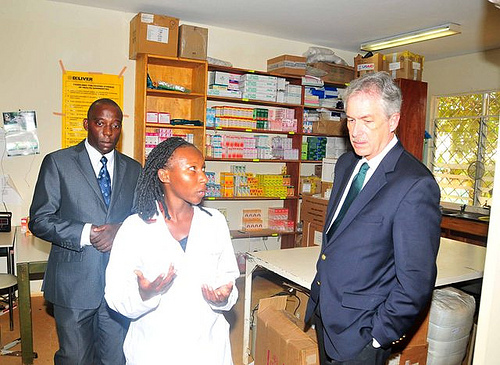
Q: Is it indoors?
A: Yes, it is indoors.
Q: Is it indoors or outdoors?
A: It is indoors.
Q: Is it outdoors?
A: No, it is indoors.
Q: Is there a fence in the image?
A: No, there are no fences.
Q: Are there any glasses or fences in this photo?
A: No, there are no fences or glasses.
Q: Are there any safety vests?
A: No, there are no safety vests.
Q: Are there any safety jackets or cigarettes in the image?
A: No, there are no safety jackets or cigarettes.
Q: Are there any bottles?
A: No, there are no bottles.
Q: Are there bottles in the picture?
A: No, there are no bottles.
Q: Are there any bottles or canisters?
A: No, there are no bottles or canisters.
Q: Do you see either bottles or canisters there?
A: No, there are no bottles or canisters.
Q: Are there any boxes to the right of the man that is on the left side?
A: Yes, there is a box to the right of the man.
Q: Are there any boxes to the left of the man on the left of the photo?
A: No, the box is to the right of the man.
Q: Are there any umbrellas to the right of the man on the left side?
A: No, there is a box to the right of the man.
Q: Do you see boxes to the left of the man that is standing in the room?
A: Yes, there is a box to the left of the man.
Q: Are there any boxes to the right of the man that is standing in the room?
A: No, the box is to the left of the man.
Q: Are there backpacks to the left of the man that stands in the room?
A: No, there is a box to the left of the man.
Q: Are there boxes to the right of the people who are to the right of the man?
A: Yes, there is a box to the right of the people.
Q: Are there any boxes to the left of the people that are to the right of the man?
A: No, the box is to the right of the people.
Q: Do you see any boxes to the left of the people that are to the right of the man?
A: No, the box is to the right of the people.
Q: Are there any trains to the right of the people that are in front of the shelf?
A: No, there is a box to the right of the people.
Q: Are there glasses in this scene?
A: No, there are no glasses.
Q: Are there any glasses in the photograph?
A: No, there are no glasses.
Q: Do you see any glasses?
A: No, there are no glasses.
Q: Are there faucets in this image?
A: No, there are no faucets.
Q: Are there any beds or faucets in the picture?
A: No, there are no faucets or beds.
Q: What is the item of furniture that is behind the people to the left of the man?
A: The piece of furniture is a shelf.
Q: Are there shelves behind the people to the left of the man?
A: Yes, there is a shelf behind the people.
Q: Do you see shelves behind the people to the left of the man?
A: Yes, there is a shelf behind the people.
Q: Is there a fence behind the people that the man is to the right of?
A: No, there is a shelf behind the people.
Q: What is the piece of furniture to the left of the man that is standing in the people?
A: The piece of furniture is a shelf.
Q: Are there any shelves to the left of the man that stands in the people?
A: Yes, there is a shelf to the left of the man.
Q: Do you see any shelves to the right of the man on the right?
A: No, the shelf is to the left of the man.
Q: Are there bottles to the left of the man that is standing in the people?
A: No, there is a shelf to the left of the man.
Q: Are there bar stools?
A: No, there are no bar stools.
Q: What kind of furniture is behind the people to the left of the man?
A: The piece of furniture is a shelf.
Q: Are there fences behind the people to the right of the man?
A: No, there is a shelf behind the people.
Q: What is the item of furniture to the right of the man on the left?
A: The piece of furniture is a shelf.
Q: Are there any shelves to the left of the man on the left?
A: No, the shelf is to the right of the man.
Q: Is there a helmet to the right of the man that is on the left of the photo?
A: No, there is a shelf to the right of the man.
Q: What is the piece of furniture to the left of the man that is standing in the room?
A: The piece of furniture is a shelf.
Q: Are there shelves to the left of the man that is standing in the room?
A: Yes, there is a shelf to the left of the man.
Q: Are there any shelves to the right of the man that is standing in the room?
A: No, the shelf is to the left of the man.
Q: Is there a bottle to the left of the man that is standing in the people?
A: No, there is a shelf to the left of the man.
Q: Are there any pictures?
A: No, there are no pictures.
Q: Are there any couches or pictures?
A: No, there are no pictures or couches.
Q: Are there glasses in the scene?
A: No, there are no glasses.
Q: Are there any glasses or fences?
A: No, there are no glasses or fences.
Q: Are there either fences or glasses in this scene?
A: No, there are no glasses or fences.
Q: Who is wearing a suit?
A: The man is wearing a suit.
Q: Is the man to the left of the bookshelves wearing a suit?
A: Yes, the man is wearing a suit.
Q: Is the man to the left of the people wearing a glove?
A: No, the man is wearing a suit.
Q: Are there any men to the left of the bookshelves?
A: Yes, there is a man to the left of the bookshelves.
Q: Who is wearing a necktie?
A: The man is wearing a necktie.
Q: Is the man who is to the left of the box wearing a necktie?
A: Yes, the man is wearing a necktie.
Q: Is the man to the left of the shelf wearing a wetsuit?
A: No, the man is wearing a necktie.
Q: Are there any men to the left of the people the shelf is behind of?
A: Yes, there is a man to the left of the people.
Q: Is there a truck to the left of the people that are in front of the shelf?
A: No, there is a man to the left of the people.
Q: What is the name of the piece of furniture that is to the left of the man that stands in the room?
A: The piece of furniture is a shelf.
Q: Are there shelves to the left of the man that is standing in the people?
A: Yes, there is a shelf to the left of the man.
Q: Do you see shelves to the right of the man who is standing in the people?
A: No, the shelf is to the left of the man.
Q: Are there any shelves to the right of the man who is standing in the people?
A: No, the shelf is to the left of the man.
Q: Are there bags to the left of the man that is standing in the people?
A: No, there is a shelf to the left of the man.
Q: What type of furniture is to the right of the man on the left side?
A: The piece of furniture is a shelf.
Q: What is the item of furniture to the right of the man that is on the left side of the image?
A: The piece of furniture is a shelf.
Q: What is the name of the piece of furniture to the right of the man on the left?
A: The piece of furniture is a shelf.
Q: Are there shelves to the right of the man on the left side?
A: Yes, there is a shelf to the right of the man.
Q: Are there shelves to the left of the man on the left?
A: No, the shelf is to the right of the man.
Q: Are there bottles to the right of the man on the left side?
A: No, there is a shelf to the right of the man.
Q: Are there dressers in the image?
A: No, there are no dressers.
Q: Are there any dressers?
A: No, there are no dressers.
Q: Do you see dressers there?
A: No, there are no dressers.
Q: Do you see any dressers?
A: No, there are no dressers.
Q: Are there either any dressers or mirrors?
A: No, there are no dressers or mirrors.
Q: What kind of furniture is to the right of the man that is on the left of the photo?
A: The piece of furniture is a shelf.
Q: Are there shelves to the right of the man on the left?
A: Yes, there is a shelf to the right of the man.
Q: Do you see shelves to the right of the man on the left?
A: Yes, there is a shelf to the right of the man.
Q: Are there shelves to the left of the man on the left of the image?
A: No, the shelf is to the right of the man.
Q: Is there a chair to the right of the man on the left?
A: No, there is a shelf to the right of the man.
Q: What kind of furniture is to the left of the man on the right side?
A: The piece of furniture is a shelf.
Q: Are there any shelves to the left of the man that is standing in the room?
A: Yes, there is a shelf to the left of the man.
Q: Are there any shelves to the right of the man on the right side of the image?
A: No, the shelf is to the left of the man.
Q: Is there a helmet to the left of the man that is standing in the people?
A: No, there is a shelf to the left of the man.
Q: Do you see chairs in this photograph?
A: No, there are no chairs.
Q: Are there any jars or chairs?
A: No, there are no chairs or jars.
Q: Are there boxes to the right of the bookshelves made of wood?
A: Yes, there are boxes to the right of the bookshelves.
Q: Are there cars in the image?
A: No, there are no cars.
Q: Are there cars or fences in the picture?
A: No, there are no cars or fences.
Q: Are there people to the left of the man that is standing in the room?
A: Yes, there are people to the left of the man.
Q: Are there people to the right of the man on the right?
A: No, the people are to the left of the man.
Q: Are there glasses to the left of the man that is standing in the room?
A: No, there are people to the left of the man.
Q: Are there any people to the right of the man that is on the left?
A: Yes, there are people to the right of the man.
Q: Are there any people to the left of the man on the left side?
A: No, the people are to the right of the man.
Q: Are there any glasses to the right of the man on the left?
A: No, there are people to the right of the man.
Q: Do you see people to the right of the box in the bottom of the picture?
A: No, the people are to the left of the box.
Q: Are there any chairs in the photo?
A: No, there are no chairs.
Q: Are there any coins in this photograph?
A: No, there are no coins.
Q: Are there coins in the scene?
A: No, there are no coins.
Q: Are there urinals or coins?
A: No, there are no coins or urinals.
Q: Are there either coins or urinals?
A: No, there are no coins or urinals.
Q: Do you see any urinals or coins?
A: No, there are no coins or urinals.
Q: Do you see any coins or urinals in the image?
A: No, there are no coins or urinals.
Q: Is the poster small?
A: Yes, the poster is small.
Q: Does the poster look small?
A: Yes, the poster is small.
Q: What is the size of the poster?
A: The poster is small.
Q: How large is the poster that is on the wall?
A: The poster is small.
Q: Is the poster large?
A: No, the poster is small.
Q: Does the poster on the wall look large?
A: No, the poster is small.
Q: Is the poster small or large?
A: The poster is small.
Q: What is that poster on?
A: The poster is on the wall.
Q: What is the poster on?
A: The poster is on the wall.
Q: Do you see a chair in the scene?
A: No, there are no chairs.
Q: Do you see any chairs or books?
A: No, there are no chairs or books.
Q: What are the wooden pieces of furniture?
A: The pieces of furniture are bookshelves.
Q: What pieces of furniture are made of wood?
A: The pieces of furniture are bookshelves.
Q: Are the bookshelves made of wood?
A: Yes, the bookshelves are made of wood.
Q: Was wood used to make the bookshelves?
A: Yes, the bookshelves are made of wood.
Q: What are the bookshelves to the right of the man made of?
A: The bookshelves are made of wood.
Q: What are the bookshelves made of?
A: The bookshelves are made of wood.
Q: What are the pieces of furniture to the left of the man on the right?
A: The pieces of furniture are bookshelves.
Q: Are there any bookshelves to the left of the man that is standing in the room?
A: Yes, there are bookshelves to the left of the man.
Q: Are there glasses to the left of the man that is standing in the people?
A: No, there are bookshelves to the left of the man.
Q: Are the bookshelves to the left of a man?
A: Yes, the bookshelves are to the left of a man.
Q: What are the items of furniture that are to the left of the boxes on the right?
A: The pieces of furniture are bookshelves.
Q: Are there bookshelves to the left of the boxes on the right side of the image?
A: Yes, there are bookshelves to the left of the boxes.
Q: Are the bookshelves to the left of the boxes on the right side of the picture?
A: Yes, the bookshelves are to the left of the boxes.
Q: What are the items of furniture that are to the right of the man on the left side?
A: The pieces of furniture are bookshelves.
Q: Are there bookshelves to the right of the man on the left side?
A: Yes, there are bookshelves to the right of the man.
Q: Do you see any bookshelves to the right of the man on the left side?
A: Yes, there are bookshelves to the right of the man.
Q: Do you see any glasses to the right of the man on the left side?
A: No, there are bookshelves to the right of the man.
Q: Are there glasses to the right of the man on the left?
A: No, there are bookshelves to the right of the man.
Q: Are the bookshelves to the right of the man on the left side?
A: Yes, the bookshelves are to the right of the man.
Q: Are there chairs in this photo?
A: No, there are no chairs.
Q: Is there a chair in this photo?
A: No, there are no chairs.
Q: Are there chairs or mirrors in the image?
A: No, there are no chairs or mirrors.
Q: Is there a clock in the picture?
A: No, there are no clocks.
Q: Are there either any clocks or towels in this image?
A: No, there are no clocks or towels.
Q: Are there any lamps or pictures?
A: No, there are no pictures or lamps.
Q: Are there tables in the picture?
A: Yes, there is a table.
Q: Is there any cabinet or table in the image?
A: Yes, there is a table.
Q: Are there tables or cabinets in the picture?
A: Yes, there is a table.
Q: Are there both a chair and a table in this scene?
A: No, there is a table but no chairs.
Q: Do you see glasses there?
A: No, there are no glasses.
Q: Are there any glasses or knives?
A: No, there are no glasses or knives.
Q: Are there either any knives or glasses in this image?
A: No, there are no glasses or knives.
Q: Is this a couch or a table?
A: This is a table.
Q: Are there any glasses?
A: No, there are no glasses.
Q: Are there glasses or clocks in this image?
A: No, there are no glasses or clocks.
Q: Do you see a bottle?
A: No, there are no bottles.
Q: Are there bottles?
A: No, there are no bottles.